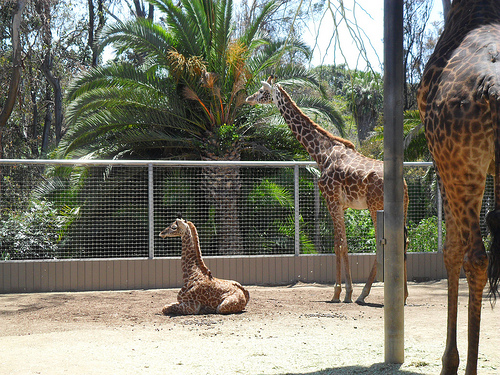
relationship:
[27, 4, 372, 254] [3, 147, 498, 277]
tree behind fence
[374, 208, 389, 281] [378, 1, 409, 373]
box on pole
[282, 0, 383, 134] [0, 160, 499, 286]
branches behind fence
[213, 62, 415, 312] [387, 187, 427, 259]
giraffe has tail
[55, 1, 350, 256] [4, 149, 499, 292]
palm tree beside fence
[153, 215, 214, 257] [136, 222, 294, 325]
head of giraffe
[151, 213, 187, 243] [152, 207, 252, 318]
face of giraffe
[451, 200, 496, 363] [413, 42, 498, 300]
leg of giraffe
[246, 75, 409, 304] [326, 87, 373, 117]
giraffe on ground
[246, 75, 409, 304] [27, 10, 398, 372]
giraffe in zoo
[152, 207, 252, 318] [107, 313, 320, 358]
giraffe sitting on ground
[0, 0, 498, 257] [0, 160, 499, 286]
tree behind fence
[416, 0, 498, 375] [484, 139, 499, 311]
giraffe has tail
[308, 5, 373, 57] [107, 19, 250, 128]
branches hanging from tree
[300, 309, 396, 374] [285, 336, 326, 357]
shadow on ground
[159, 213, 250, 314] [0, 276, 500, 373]
giraffe on ground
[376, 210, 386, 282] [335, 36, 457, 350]
box attached to pole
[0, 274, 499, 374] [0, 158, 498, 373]
sand in area